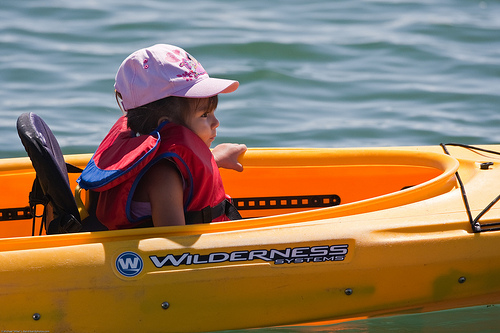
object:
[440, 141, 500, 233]
rope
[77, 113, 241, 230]
vest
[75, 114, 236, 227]
life jacket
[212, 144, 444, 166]
kayak side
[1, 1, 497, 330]
water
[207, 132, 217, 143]
mouth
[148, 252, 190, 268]
lettering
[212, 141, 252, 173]
hand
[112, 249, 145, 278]
logo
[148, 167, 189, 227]
arm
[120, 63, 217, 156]
head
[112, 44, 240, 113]
cap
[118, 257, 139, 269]
white w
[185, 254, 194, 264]
word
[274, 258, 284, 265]
word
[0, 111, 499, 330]
kayak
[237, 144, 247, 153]
finger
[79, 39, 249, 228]
child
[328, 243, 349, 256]
writing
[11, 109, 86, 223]
back